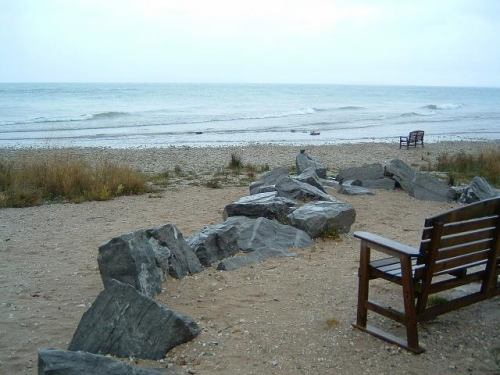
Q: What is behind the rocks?
A: A bench.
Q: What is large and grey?
A: Rocks.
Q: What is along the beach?
A: Shoreline.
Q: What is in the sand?
A: Rocks.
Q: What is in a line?
A: Rocks.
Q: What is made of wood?
A: A bench.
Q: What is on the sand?
A: Rocks.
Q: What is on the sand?
A: A bench.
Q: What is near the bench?
A: Grass.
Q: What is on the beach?
A: Rocks.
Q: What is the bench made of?
A: Wood.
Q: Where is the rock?
A: On the sand.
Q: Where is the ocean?
A: In the back.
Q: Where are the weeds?
A: Near the beach.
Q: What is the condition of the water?
A: Wavy.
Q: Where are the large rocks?
A: On the beach.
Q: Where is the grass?
A: On the beach.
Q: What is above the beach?
A: The sky.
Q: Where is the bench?
A: On the beach.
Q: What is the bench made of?
A: Wood.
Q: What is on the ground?
A: Sand.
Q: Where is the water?
A: At the beach.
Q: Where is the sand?
A: At the beach.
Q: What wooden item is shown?
A: A bench.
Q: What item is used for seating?
A: A bench.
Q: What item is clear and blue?
A: The sky.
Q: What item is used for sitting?
A: A bench.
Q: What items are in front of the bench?
A: Rocks.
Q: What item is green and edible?
A: Grass.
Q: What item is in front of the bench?
A: Rocks.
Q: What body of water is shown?
A: The ocean.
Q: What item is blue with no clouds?
A: The sky.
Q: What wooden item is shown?
A: A bench.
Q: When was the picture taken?
A: Daytime.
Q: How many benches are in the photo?
A: Two.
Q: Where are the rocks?
A: On the ground.